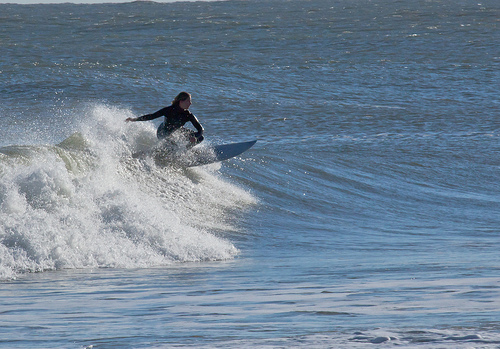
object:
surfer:
[121, 90, 206, 160]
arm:
[121, 108, 166, 123]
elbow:
[196, 127, 205, 136]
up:
[226, 139, 257, 161]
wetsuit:
[131, 104, 208, 158]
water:
[0, 247, 499, 349]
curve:
[274, 96, 494, 233]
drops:
[2, 90, 90, 143]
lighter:
[8, 50, 202, 96]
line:
[261, 124, 481, 171]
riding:
[129, 131, 212, 153]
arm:
[188, 111, 203, 142]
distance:
[0, 0, 500, 69]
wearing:
[132, 103, 206, 154]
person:
[124, 90, 208, 155]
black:
[163, 108, 185, 129]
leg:
[173, 127, 207, 154]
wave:
[4, 122, 268, 273]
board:
[129, 137, 259, 168]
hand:
[123, 117, 135, 124]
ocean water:
[4, 4, 500, 349]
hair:
[171, 93, 190, 107]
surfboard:
[131, 136, 264, 175]